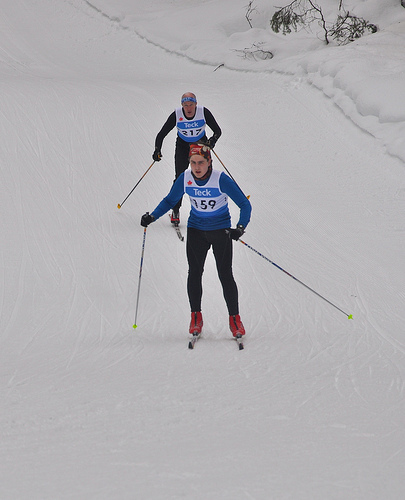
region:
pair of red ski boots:
[189, 308, 245, 335]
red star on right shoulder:
[187, 178, 192, 185]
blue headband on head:
[180, 92, 197, 118]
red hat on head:
[190, 144, 211, 178]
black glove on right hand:
[142, 212, 153, 226]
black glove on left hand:
[226, 226, 244, 239]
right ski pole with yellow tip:
[130, 211, 150, 327]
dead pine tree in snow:
[272, 1, 379, 54]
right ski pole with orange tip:
[118, 153, 161, 208]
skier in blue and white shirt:
[140, 144, 252, 354]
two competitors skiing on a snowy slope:
[117, 91, 355, 350]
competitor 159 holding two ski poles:
[132, 141, 353, 349]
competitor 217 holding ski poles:
[116, 93, 251, 241]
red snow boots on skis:
[187, 310, 246, 349]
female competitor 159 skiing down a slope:
[131, 142, 355, 349]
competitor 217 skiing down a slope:
[117, 91, 251, 241]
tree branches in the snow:
[268, 0, 378, 47]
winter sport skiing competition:
[113, 90, 352, 347]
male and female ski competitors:
[116, 90, 354, 350]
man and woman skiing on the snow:
[1, 69, 403, 498]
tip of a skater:
[181, 326, 197, 349]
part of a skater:
[235, 392, 265, 434]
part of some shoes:
[229, 326, 248, 345]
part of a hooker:
[318, 286, 355, 329]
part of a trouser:
[217, 278, 252, 308]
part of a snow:
[199, 366, 233, 412]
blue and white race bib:
[188, 189, 222, 217]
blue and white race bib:
[176, 124, 207, 137]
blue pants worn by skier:
[188, 235, 237, 307]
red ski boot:
[188, 312, 203, 333]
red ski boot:
[229, 317, 244, 332]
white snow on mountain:
[18, 277, 123, 478]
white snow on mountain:
[122, 361, 377, 479]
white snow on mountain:
[13, 18, 117, 193]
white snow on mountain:
[241, 62, 396, 182]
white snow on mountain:
[285, 86, 375, 252]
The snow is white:
[139, 418, 246, 485]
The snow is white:
[111, 372, 239, 496]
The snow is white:
[130, 352, 286, 457]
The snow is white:
[174, 418, 272, 478]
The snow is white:
[101, 350, 219, 441]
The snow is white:
[174, 424, 226, 464]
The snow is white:
[206, 405, 303, 495]